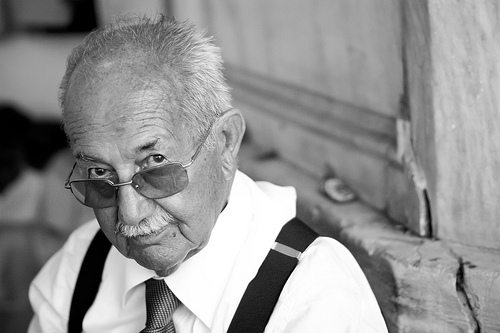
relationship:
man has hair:
[19, 17, 409, 332] [71, 21, 214, 57]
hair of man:
[71, 21, 214, 57] [19, 17, 409, 332]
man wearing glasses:
[19, 17, 409, 332] [63, 162, 190, 208]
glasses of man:
[63, 162, 190, 208] [19, 17, 409, 332]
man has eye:
[19, 17, 409, 332] [88, 164, 114, 182]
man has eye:
[19, 17, 409, 332] [143, 153, 167, 172]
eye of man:
[88, 164, 114, 182] [19, 17, 409, 332]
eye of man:
[143, 153, 167, 172] [19, 17, 409, 332]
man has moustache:
[19, 17, 409, 332] [113, 212, 171, 239]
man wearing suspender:
[19, 17, 409, 332] [221, 216, 329, 329]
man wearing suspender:
[19, 17, 409, 332] [51, 229, 113, 332]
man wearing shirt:
[19, 17, 409, 332] [27, 166, 389, 331]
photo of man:
[5, 1, 496, 332] [19, 17, 409, 332]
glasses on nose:
[63, 162, 190, 208] [112, 186, 163, 227]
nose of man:
[112, 186, 163, 227] [19, 17, 409, 332]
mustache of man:
[116, 211, 178, 238] [19, 17, 409, 332]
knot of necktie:
[140, 319, 174, 332] [139, 278, 179, 332]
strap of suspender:
[226, 220, 318, 333] [221, 216, 329, 329]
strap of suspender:
[67, 231, 109, 332] [51, 229, 113, 332]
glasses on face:
[63, 162, 190, 208] [67, 86, 215, 273]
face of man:
[67, 86, 215, 273] [19, 17, 409, 332]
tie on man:
[139, 278, 179, 332] [19, 17, 409, 332]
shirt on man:
[27, 166, 389, 331] [19, 17, 409, 332]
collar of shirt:
[164, 173, 269, 333] [27, 166, 389, 331]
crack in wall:
[420, 190, 482, 333] [230, 6, 500, 332]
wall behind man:
[230, 6, 500, 332] [19, 17, 409, 332]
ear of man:
[217, 103, 247, 182] [19, 17, 409, 332]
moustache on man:
[113, 212, 171, 239] [19, 17, 409, 332]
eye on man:
[88, 164, 114, 182] [19, 17, 409, 332]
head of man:
[48, 8, 255, 274] [19, 17, 409, 332]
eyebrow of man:
[74, 151, 109, 167] [19, 17, 409, 332]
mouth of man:
[119, 219, 172, 247] [19, 17, 409, 332]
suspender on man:
[221, 216, 329, 329] [19, 17, 409, 332]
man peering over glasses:
[19, 17, 409, 332] [63, 162, 190, 208]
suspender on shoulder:
[221, 216, 329, 329] [245, 198, 377, 314]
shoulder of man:
[245, 198, 377, 314] [19, 17, 409, 332]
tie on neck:
[139, 278, 179, 332] [135, 241, 231, 285]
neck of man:
[135, 241, 231, 285] [19, 17, 409, 332]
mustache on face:
[116, 211, 178, 238] [67, 86, 215, 273]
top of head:
[85, 55, 157, 80] [48, 8, 255, 274]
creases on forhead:
[124, 98, 170, 132] [59, 100, 197, 147]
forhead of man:
[59, 100, 197, 147] [19, 17, 409, 332]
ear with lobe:
[217, 103, 247, 182] [218, 153, 240, 180]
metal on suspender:
[270, 241, 305, 265] [221, 216, 329, 329]